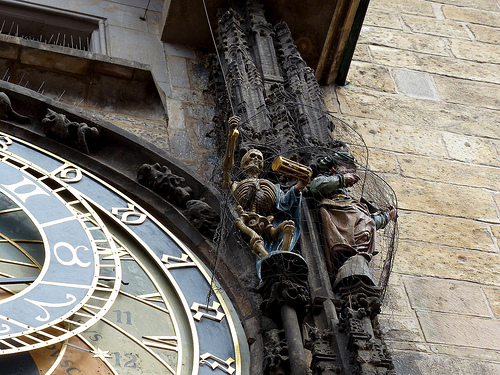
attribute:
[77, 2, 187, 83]
wall — tan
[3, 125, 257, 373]
clock — silver, very large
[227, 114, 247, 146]
hand — raised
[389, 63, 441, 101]
brick — light grey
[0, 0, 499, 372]
building — brick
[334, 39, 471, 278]
wall — stony